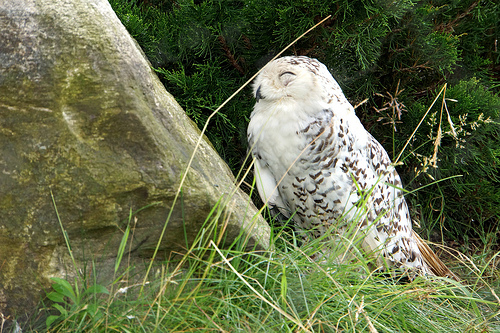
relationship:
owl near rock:
[241, 63, 391, 193] [19, 16, 155, 166]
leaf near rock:
[56, 275, 88, 311] [19, 16, 155, 166]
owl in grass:
[241, 63, 391, 193] [257, 246, 316, 293]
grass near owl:
[257, 246, 316, 293] [241, 63, 391, 193]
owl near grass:
[241, 63, 391, 193] [257, 246, 316, 293]